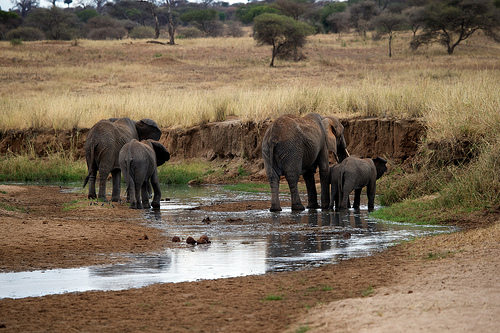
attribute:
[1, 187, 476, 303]
water — river, shallow, sparse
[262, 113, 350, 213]
elephant — big, large, huge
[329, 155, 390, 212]
elephant — small, grey, a baby, baby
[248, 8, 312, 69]
tree — small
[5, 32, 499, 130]
grass — brown, dry, dried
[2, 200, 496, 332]
river bank — brown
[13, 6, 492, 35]
bushes — small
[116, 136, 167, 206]
elephant — walking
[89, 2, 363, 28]
trees — green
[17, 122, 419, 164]
ledge — dirt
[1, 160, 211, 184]
grass — green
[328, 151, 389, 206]
elephant — baby